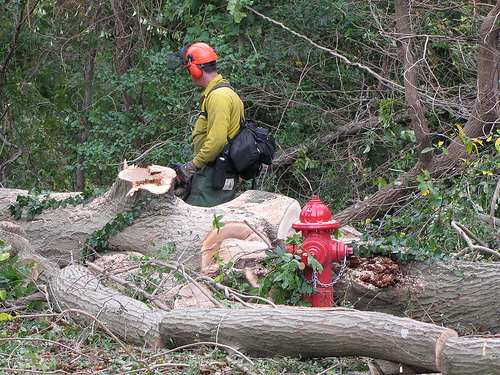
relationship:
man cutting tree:
[176, 44, 251, 209] [6, 164, 499, 373]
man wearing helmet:
[176, 44, 251, 209] [181, 42, 219, 64]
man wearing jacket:
[176, 44, 251, 209] [192, 73, 244, 164]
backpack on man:
[232, 120, 277, 180] [176, 44, 251, 209]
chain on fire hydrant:
[312, 263, 347, 290] [287, 190, 354, 307]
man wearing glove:
[176, 44, 251, 209] [178, 163, 198, 184]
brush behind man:
[4, 4, 499, 260] [176, 44, 251, 209]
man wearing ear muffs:
[176, 44, 251, 209] [188, 64, 206, 81]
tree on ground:
[6, 164, 499, 373] [7, 169, 499, 375]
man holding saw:
[176, 44, 251, 209] [162, 166, 189, 195]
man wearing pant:
[176, 44, 251, 209] [189, 159, 234, 207]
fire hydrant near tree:
[287, 190, 354, 307] [6, 164, 499, 373]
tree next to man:
[6, 164, 499, 373] [176, 44, 251, 209]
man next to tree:
[176, 44, 251, 209] [6, 164, 499, 373]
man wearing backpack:
[176, 44, 251, 209] [232, 120, 277, 180]